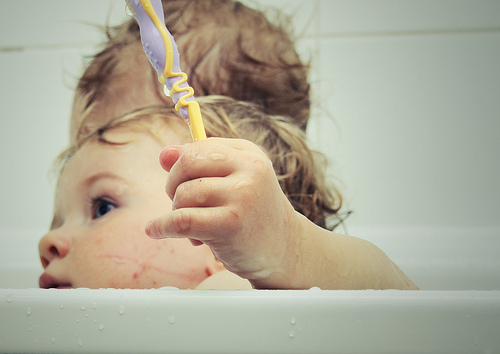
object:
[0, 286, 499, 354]
tub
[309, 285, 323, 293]
water drop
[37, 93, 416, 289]
kid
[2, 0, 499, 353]
bathroom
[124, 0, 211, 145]
toothbrush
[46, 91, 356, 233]
hair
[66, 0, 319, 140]
hair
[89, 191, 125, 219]
eye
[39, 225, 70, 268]
nose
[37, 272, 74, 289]
mouth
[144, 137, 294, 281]
hand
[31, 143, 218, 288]
face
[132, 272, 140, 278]
mark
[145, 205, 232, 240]
fingers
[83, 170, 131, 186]
eyebrow